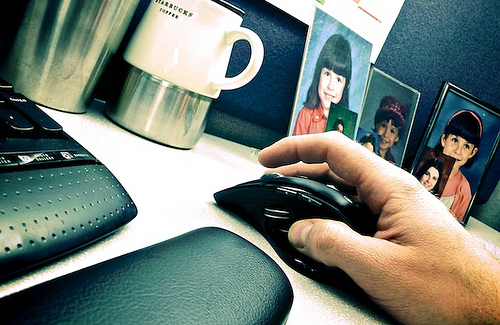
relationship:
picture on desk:
[283, 5, 375, 142] [2, 79, 496, 322]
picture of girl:
[272, 2, 497, 236] [302, 30, 360, 141]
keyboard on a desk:
[14, 103, 111, 238] [89, 103, 386, 315]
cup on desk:
[122, 23, 312, 134] [2, 79, 496, 322]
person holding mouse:
[253, 127, 497, 322] [201, 130, 401, 277]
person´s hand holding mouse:
[255, 125, 499, 324] [212, 170, 379, 293]